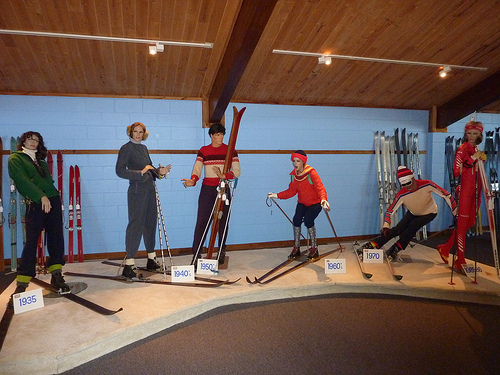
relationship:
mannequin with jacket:
[269, 150, 334, 260] [292, 172, 331, 217]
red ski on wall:
[73, 167, 89, 263] [238, 115, 494, 239]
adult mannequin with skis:
[115, 122, 172, 279] [206, 105, 247, 259]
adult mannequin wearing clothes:
[115, 122, 172, 279] [128, 148, 152, 236]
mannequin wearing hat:
[6, 110, 496, 320] [390, 159, 417, 186]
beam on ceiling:
[207, 0, 274, 124] [1, 0, 498, 130]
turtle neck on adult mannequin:
[17, 143, 46, 169] [7, 131, 70, 299]